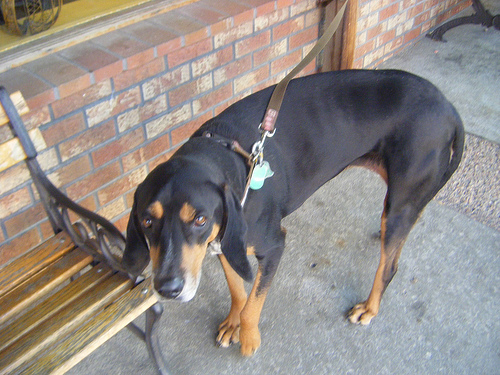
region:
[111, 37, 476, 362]
a black and brown dog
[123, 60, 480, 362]
a dog with poor body language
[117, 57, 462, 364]
a dog that is cowering a bit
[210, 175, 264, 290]
a long ear of a dog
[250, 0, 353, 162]
a leash attached to a dog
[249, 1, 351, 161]
a leash attached to a collar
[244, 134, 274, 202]
a dog's tag and license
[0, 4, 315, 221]
a nice brick wall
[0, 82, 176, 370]
a metal and wood bench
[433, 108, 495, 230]
a section of aggregate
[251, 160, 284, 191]
blue tags on a collar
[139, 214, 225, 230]
two eyes on a face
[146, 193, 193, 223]
brown spots on a dog head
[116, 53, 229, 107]
a brick wall under a window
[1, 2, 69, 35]
a metal sculpture sitting in a window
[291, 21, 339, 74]
a brown dog lease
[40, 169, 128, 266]
black ironwork on the side of bench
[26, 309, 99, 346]
brown wooden slats in a bench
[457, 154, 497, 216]
gravel spread on the ground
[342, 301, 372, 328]
a paw at the end of the leg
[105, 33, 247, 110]
red brick wall on building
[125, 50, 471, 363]
black and brown dog on sidewalk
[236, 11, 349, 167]
brown leash on dog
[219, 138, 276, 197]
dog collar with tags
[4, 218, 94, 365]
worn wood on bench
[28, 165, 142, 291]
decorative metal bench arm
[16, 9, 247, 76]
window sill made of brick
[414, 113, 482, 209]
tucked black dog tail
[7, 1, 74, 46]
decoration in building window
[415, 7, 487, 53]
metal foot of bench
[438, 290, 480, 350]
part of the ground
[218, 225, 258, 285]
left ear of the dog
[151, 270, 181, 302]
nose of the dog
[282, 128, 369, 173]
stomach of the dog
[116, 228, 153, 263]
right ear of a dog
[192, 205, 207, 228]
left ear of a dog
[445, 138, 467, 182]
tail of a dog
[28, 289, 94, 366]
lower part of the bench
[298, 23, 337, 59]
part of a belt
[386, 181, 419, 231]
left thigh of a dog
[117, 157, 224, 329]
sad rottweiler colored dog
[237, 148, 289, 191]
two tags on dogs collar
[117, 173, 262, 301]
sad looking dog on a leash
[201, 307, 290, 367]
two dog paws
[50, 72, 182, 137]
brick wall behind the dog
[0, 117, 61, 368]
wooden bench next to a dog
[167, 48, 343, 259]
dog with a brown collar and a brown leash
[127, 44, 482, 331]
dog standing in cowardly pose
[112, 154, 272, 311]
dog with brown eyes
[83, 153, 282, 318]
brown eyed dog with brown spots